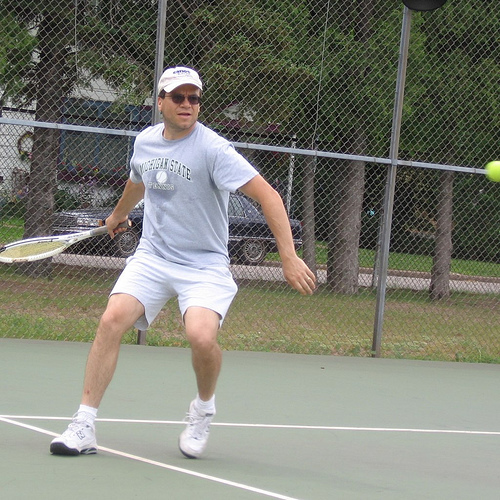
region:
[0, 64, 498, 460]
Man is playing tennis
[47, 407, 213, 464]
Man is wearing shoes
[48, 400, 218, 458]
Man is wearing white shoes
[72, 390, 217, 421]
Man is wearing socks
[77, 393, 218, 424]
Man is wearing white socks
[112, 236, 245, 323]
Man is wearing shorts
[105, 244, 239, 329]
Man is wearing white shorts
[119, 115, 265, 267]
Man is wearing a shirt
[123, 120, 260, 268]
Man is wearing a gray shirt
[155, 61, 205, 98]
Man is wearing a hat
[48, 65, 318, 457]
a male tennis player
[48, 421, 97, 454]
a black and white tennis shoe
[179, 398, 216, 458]
a black and white tennis shoe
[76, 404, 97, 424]
a man's white sock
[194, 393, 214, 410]
a man's white sock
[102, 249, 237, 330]
a pair of white shorts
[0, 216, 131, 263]
a white and grey tennis racket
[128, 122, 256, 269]
a men's grey t-shirt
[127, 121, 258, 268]
a Michigan State shirt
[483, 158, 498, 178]
a yellow tennis ball in air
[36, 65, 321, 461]
Man wearing dark eye glasses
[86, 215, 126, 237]
Handle of tennis racket is gray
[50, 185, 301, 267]
Navy blue car is parked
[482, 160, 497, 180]
Round tennis ball is green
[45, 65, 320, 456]
Man wearing white hat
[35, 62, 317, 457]
Man holding tennis racket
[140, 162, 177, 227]
Sweat on gray shirt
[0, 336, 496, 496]
Tennis court is green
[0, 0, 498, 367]
Fence behind man wearing white hat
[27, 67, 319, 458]
Man wearing white shorts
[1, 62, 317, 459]
a man playing tennis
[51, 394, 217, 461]
man wearing white shoes and socks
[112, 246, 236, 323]
man wearing white shorts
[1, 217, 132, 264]
man holding a tennis racket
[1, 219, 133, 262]
a white tennis racket with a gray handle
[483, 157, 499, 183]
a yellow tennis ball flying above the ground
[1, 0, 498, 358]
a metal fence on a tennis court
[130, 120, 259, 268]
man wearing a gray shirt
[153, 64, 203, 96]
man wearing a white cap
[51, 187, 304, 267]
a black car parked on the side of a street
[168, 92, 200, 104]
a black pair of sunglasses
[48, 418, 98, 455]
a white shoe on someone's foot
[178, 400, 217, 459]
a white shoe on someone's foot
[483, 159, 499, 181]
a tennis ball in the air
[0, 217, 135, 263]
a white tennis racket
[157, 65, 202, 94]
a white baseball cap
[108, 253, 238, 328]
a white pair of shorts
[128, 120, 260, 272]
a gray short sleeve shirt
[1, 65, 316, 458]
a man holding a tennis racket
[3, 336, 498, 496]
part of a tennis court